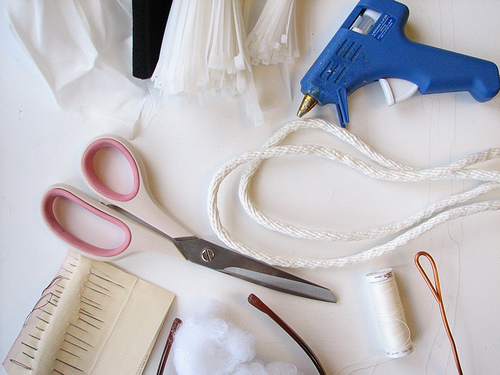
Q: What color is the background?
A: White.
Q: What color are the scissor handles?
A: Pink.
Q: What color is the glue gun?
A: Blue.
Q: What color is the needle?
A: Gold.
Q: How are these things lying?
A: Next to each other.